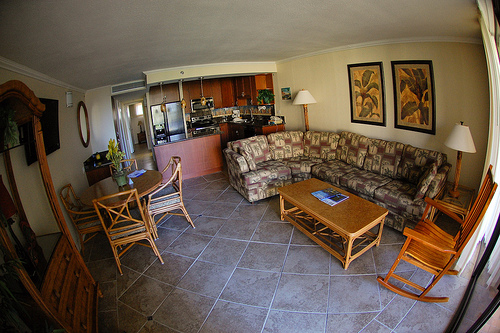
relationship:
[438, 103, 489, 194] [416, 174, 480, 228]
lamp on table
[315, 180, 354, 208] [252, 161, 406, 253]
book on table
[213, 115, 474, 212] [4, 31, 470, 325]
couch in room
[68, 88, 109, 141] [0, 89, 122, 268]
mirror on wall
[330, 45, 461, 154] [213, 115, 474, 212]
paintings above couch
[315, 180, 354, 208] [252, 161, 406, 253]
magazines on table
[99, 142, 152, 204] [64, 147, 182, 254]
plant on table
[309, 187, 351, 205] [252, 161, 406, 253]
book on table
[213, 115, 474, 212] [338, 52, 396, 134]
sofa with palm tree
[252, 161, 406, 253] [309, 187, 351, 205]
table with book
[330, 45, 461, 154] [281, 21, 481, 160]
pictures on wall